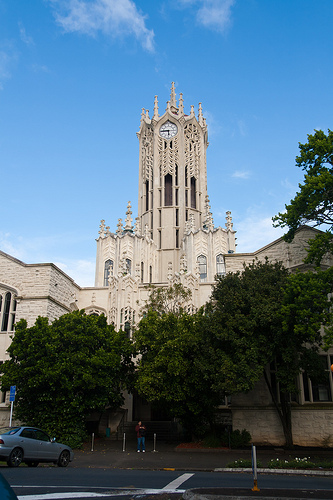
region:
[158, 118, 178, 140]
a large clock on the building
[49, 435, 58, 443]
the side mirror on the car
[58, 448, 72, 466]
the front wheel on the the car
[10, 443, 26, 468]
the back wheel on the car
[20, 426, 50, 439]
the windows on the car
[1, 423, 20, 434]
the back window on the car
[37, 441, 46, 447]
a door handle on the car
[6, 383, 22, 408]
a handicap parking sign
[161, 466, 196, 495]
the lines on the road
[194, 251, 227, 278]
two windows on the building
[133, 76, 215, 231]
an ornate clock tower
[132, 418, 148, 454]
a pedestrian at street level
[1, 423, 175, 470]
a gray sedan approaching the driveway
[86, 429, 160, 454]
poles that block entrance by large vehicles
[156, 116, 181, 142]
the clock reads 5:45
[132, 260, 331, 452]
big leafy shade trees line the street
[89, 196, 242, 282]
smaller towers are the same design as the clock tower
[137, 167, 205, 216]
open archways in the clock tower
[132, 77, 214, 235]
the clock tower is beige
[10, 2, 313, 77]
a few scattered clouds in the sky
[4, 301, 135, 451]
this is a bushy tree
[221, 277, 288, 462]
this is a bushy tree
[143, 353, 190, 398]
this is a bushy tree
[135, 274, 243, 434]
this is a bushy tree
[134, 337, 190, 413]
this is a bushy tree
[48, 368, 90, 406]
this is a bushy tree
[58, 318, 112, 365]
this is a bushy tree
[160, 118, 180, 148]
clock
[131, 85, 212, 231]
tan clock tower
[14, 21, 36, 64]
white clouds in blue sky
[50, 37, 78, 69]
white clouds in blue sky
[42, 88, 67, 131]
white clouds in blue sky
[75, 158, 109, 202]
white clouds in blue sky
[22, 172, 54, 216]
white clouds in blue sky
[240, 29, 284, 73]
white clouds in blue sky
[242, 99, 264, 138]
white clouds in blue sky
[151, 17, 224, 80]
white clouds in blue sky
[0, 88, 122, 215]
The clear blue sky above.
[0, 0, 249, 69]
A few thin white clouds.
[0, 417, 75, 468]
A car parked near the curb.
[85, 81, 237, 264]
An ornate stone clock tower.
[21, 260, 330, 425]
A group of tall green trees.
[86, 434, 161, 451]
Three poles in the pavement.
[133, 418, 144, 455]
A person standing outside of the building.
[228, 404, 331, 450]
A stone wall facing the street.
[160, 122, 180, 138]
The face of the clock.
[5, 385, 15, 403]
A vivid blue street sign.